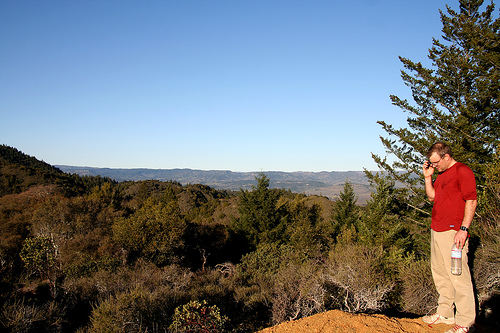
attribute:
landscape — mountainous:
[2, 142, 498, 327]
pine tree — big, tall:
[357, 2, 497, 323]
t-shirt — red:
[429, 166, 478, 233]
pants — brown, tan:
[431, 230, 475, 327]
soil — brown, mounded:
[289, 316, 368, 332]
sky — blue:
[2, 2, 497, 171]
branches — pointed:
[199, 246, 210, 269]